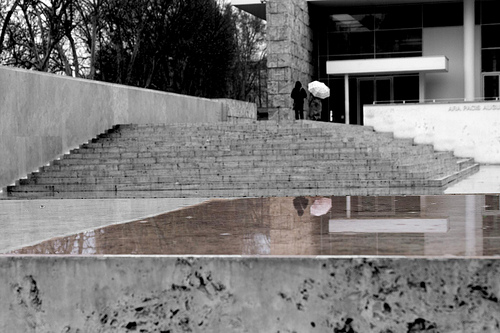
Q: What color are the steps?
A: Grey.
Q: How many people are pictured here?
A: Two.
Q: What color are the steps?
A: Grey.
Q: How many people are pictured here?
A: Two.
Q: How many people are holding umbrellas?
A: One.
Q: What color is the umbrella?
A: White.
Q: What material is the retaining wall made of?
A: Concrete.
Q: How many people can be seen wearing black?
A: One.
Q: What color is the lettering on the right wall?
A: Grey.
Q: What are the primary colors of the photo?
A: Black and white.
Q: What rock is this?
A: Granite.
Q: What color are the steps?
A: Gray.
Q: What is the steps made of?
A: Marble.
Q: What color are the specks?
A: Black.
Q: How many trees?
A: Many trees.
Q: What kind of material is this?
A: Marble.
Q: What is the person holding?
A: An umbrella.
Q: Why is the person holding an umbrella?
A: It is raining.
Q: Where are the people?
A: At the top of the stairs.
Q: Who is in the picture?
A: Two people.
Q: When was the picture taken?
A: Daytime.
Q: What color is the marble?
A: Gray.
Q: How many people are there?
A: Two.